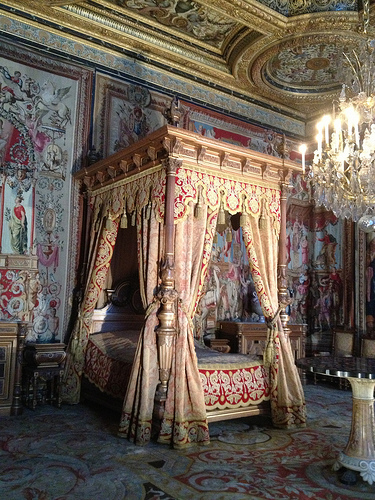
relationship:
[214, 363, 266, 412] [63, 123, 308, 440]
comforter on bed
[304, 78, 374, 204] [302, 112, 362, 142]
chandelier has lights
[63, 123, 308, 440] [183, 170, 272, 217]
bed has canopy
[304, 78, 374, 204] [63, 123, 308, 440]
chandelier above bed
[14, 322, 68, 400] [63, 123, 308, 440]
table next to bed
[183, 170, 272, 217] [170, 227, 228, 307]
canopy has drapes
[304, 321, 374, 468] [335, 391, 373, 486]
table has column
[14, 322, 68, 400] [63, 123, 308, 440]
table by bed